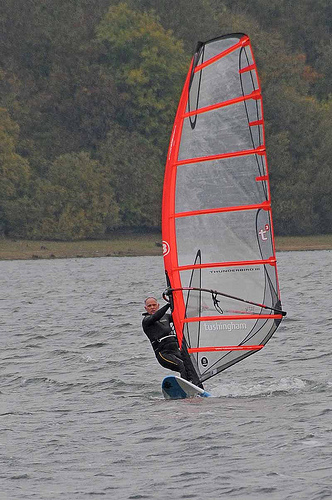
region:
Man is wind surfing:
[135, 290, 210, 386]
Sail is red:
[163, 30, 281, 381]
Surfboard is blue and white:
[160, 372, 209, 404]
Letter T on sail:
[259, 226, 266, 241]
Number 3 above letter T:
[263, 222, 269, 231]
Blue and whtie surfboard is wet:
[160, 374, 212, 398]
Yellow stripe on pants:
[155, 346, 178, 368]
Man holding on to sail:
[139, 293, 210, 388]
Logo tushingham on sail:
[201, 320, 245, 329]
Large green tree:
[21, 145, 118, 241]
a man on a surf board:
[133, 267, 213, 499]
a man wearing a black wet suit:
[146, 285, 169, 381]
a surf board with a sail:
[141, 73, 268, 492]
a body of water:
[0, 246, 149, 394]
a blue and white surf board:
[135, 365, 207, 421]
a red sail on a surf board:
[170, 26, 270, 492]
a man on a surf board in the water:
[130, 188, 237, 404]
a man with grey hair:
[136, 291, 160, 318]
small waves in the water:
[24, 315, 116, 386]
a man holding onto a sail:
[126, 280, 198, 403]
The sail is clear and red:
[153, 31, 298, 377]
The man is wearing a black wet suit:
[131, 294, 211, 395]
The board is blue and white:
[155, 370, 222, 415]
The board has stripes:
[160, 381, 217, 415]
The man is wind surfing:
[116, 55, 281, 392]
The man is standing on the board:
[133, 48, 293, 399]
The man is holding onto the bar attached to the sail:
[141, 271, 228, 407]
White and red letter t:
[252, 215, 275, 243]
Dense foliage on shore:
[34, 43, 303, 243]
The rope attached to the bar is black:
[206, 285, 227, 318]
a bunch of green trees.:
[0, 18, 154, 233]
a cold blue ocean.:
[8, 356, 149, 459]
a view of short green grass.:
[14, 238, 130, 252]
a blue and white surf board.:
[152, 371, 209, 405]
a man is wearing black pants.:
[153, 346, 176, 362]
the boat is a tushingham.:
[196, 312, 246, 328]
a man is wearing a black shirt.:
[140, 310, 171, 335]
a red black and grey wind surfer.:
[146, 27, 321, 261]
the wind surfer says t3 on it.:
[247, 221, 282, 254]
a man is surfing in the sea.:
[124, 17, 326, 419]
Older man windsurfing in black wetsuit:
[140, 289, 204, 387]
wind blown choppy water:
[22, 376, 310, 479]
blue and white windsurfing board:
[153, 373, 232, 406]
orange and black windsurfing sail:
[172, 33, 277, 320]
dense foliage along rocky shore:
[5, 34, 157, 239]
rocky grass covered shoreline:
[10, 239, 159, 262]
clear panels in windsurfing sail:
[178, 166, 255, 202]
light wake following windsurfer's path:
[212, 370, 320, 399]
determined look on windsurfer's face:
[141, 295, 171, 349]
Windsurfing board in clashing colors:
[159, 18, 272, 410]